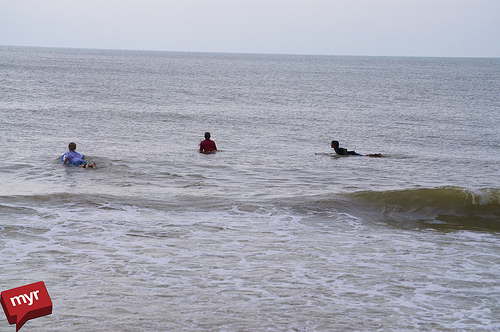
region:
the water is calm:
[63, 72, 115, 104]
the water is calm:
[138, 65, 292, 115]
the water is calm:
[234, 54, 326, 119]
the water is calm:
[86, 58, 173, 101]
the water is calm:
[141, 236, 233, 289]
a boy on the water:
[56, 131, 113, 168]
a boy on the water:
[178, 105, 229, 201]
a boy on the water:
[310, 131, 417, 199]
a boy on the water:
[181, 128, 238, 181]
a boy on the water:
[33, 127, 129, 197]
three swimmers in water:
[41, 131, 431, 179]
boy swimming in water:
[33, 135, 124, 175]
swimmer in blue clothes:
[42, 140, 113, 173]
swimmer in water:
[190, 127, 236, 158]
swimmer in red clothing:
[185, 122, 232, 162]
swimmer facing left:
[305, 133, 387, 169]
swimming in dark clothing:
[312, 138, 387, 165]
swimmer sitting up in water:
[186, 118, 232, 170]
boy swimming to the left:
[319, 134, 395, 167]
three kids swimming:
[37, 127, 386, 182]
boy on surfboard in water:
[53, 128, 116, 179]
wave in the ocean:
[338, 177, 490, 244]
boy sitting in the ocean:
[191, 126, 232, 166]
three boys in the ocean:
[46, 126, 421, 177]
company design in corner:
[5, 273, 60, 328]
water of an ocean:
[171, 248, 459, 297]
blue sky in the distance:
[253, 4, 460, 54]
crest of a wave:
[461, 181, 489, 206]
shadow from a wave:
[385, 202, 497, 240]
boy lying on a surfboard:
[314, 133, 394, 168]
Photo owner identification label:
[5, 277, 55, 327]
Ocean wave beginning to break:
[318, 179, 499, 227]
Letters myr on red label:
[9, 287, 41, 309]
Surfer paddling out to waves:
[56, 140, 103, 175]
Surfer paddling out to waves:
[192, 130, 225, 159]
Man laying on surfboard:
[306, 134, 395, 168]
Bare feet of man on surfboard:
[79, 160, 101, 172]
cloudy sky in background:
[4, 6, 499, 58]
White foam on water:
[29, 214, 496, 326]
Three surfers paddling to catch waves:
[56, 127, 398, 177]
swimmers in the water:
[34, 80, 439, 216]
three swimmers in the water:
[9, 107, 447, 191]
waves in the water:
[30, 125, 497, 240]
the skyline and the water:
[15, 24, 472, 77]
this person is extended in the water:
[297, 119, 399, 182]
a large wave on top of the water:
[305, 164, 487, 215]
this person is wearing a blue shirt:
[50, 140, 110, 183]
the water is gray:
[81, 218, 380, 298]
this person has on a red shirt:
[181, 109, 251, 173]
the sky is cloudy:
[101, 11, 446, 39]